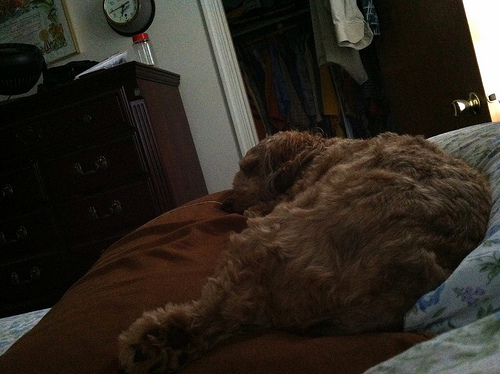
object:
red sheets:
[0, 189, 431, 374]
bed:
[0, 119, 500, 374]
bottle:
[131, 32, 160, 68]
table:
[0, 60, 182, 141]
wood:
[191, 0, 260, 153]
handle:
[73, 155, 107, 179]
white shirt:
[330, 0, 374, 51]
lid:
[132, 33, 149, 43]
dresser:
[33, 118, 149, 202]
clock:
[99, 1, 159, 37]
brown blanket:
[0, 186, 426, 374]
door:
[337, 0, 492, 139]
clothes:
[246, 0, 383, 155]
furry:
[315, 135, 465, 277]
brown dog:
[115, 130, 494, 374]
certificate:
[0, 0, 81, 64]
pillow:
[363, 120, 500, 374]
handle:
[451, 91, 481, 119]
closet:
[223, 0, 495, 139]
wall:
[0, 0, 264, 193]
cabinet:
[0, 60, 210, 317]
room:
[0, 0, 500, 374]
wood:
[151, 99, 209, 207]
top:
[132, 32, 151, 43]